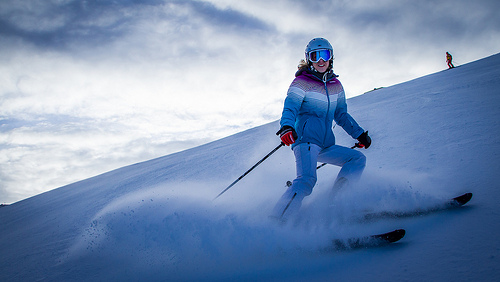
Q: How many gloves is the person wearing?
A: Two.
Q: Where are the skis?
A: On the person's feet.